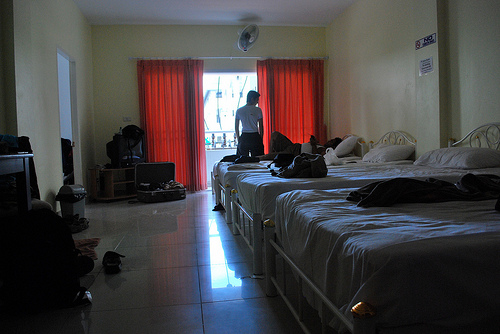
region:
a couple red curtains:
[127, 47, 325, 198]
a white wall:
[87, 19, 358, 197]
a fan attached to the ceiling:
[225, 14, 272, 59]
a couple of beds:
[212, 118, 497, 331]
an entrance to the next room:
[48, 41, 90, 216]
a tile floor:
[52, 175, 277, 332]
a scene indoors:
[20, 5, 498, 325]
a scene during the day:
[10, 9, 447, 326]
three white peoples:
[326, 126, 498, 181]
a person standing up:
[218, 80, 280, 184]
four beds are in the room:
[209, 130, 499, 324]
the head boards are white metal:
[338, 120, 499, 175]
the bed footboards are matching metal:
[207, 166, 359, 332]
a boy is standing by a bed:
[229, 86, 269, 163]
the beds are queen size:
[213, 139, 497, 329]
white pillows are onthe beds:
[324, 130, 493, 176]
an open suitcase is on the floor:
[122, 154, 190, 207]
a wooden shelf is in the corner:
[91, 162, 142, 206]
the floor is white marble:
[65, 189, 300, 331]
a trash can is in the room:
[56, 177, 92, 231]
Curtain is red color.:
[126, 58, 343, 182]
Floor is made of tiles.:
[143, 223, 237, 325]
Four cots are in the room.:
[213, 121, 483, 323]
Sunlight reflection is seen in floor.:
[166, 200, 249, 304]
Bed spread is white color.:
[218, 160, 383, 280]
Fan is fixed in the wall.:
[232, 24, 263, 58]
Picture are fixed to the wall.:
[409, 34, 441, 84]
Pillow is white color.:
[323, 131, 488, 195]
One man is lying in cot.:
[241, 122, 346, 164]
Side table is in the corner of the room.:
[97, 151, 184, 209]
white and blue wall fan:
[231, 23, 265, 59]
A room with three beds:
[192, 124, 446, 291]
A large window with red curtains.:
[165, 54, 310, 188]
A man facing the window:
[226, 96, 267, 146]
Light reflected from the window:
[202, 222, 247, 297]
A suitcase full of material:
[135, 162, 183, 207]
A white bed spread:
[280, 185, 460, 282]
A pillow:
[372, 138, 407, 165]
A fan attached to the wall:
[231, 24, 278, 56]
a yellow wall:
[33, 21, 63, 45]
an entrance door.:
[52, 54, 104, 184]